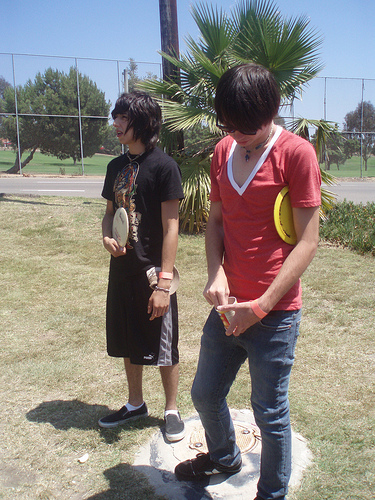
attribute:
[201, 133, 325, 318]
shirt — red, v neck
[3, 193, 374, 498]
ground — grass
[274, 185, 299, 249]
frisbee — yellow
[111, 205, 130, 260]
frisbee — white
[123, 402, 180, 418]
socks — white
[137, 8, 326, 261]
tree — palm tree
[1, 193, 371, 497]
grass — dry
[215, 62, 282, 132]
hair — black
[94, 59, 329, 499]
boys — playing frisbee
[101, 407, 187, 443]
sneakers — black, vans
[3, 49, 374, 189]
fence — mesh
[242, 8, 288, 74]
frond — palm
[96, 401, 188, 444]
shoes — slip ons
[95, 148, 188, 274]
shirt — black